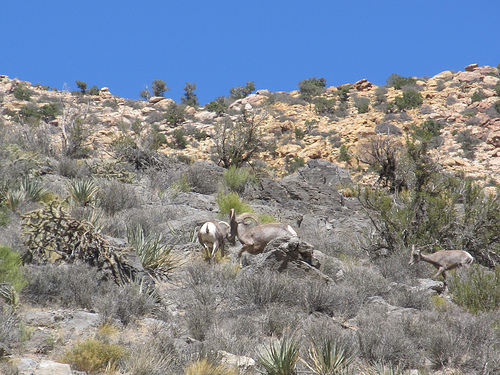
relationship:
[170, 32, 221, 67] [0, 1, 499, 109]
white clouds in blue sky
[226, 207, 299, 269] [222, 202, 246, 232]
animal has horns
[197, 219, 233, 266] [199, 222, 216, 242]
animal has butt